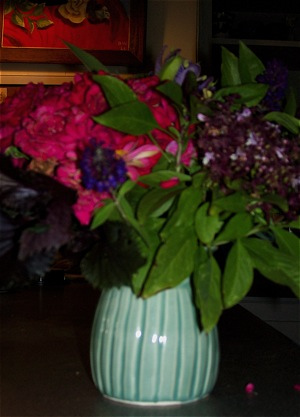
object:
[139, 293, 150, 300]
tip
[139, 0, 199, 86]
wall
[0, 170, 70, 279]
flower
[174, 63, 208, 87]
violet flower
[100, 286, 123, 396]
bands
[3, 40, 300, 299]
flowers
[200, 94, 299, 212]
purple flower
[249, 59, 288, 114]
purple flower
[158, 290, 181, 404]
line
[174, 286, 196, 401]
line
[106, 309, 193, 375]
highlights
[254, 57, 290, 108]
blue flower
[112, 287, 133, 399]
bands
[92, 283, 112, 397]
bands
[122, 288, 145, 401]
bands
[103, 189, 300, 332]
leaf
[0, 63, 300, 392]
arrangement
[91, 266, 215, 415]
vase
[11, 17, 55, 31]
painting leaves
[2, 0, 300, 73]
background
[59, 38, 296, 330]
leaves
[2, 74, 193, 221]
flower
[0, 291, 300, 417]
table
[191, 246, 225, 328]
leaf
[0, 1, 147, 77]
artwork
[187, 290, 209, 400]
line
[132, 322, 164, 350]
lights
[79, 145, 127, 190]
flower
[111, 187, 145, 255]
stem